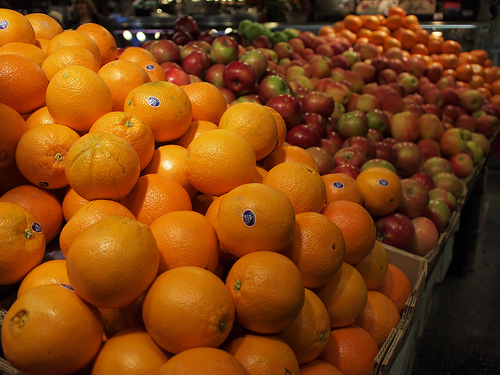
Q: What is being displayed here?
A: Fruit.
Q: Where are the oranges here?
A: Left end.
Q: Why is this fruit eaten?
A: Nutrition.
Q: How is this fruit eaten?
A: Raw.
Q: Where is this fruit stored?
A: Crates.